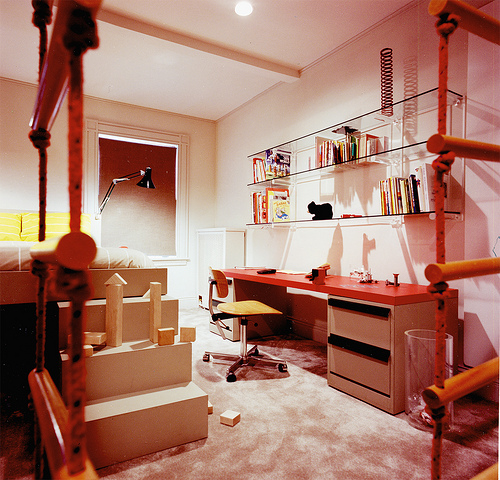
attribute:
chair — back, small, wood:
[217, 285, 261, 366]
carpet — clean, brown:
[270, 411, 300, 456]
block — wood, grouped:
[110, 416, 155, 456]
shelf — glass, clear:
[320, 201, 376, 223]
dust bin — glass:
[392, 326, 428, 358]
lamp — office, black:
[99, 171, 158, 202]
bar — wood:
[395, 6, 461, 63]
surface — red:
[276, 265, 286, 281]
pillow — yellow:
[1, 217, 38, 234]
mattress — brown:
[11, 251, 33, 262]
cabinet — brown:
[11, 293, 21, 302]